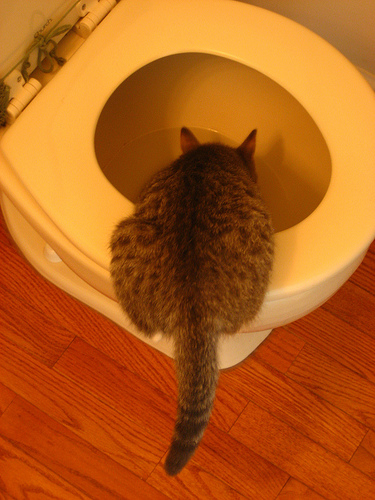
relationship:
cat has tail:
[108, 124, 264, 476] [162, 321, 215, 474]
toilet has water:
[3, 3, 374, 375] [124, 123, 247, 214]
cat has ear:
[108, 124, 264, 476] [180, 124, 198, 154]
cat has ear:
[108, 124, 264, 476] [241, 127, 261, 158]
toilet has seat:
[3, 3, 374, 375] [3, 4, 374, 312]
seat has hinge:
[3, 4, 374, 312] [8, 73, 44, 117]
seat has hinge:
[3, 4, 374, 312] [82, 4, 118, 32]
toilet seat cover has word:
[1, 1, 78, 80] [34, 17, 58, 43]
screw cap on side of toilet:
[6, 74, 25, 97] [3, 3, 374, 375]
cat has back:
[108, 124, 264, 476] [144, 161, 251, 277]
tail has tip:
[162, 321, 215, 474] [163, 443, 192, 476]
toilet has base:
[3, 3, 374, 375] [4, 195, 271, 378]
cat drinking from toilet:
[108, 124, 264, 476] [3, 3, 374, 375]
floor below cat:
[1, 204, 374, 499] [108, 124, 264, 476]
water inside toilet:
[124, 123, 247, 214] [3, 3, 374, 375]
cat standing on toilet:
[108, 124, 264, 476] [3, 3, 374, 375]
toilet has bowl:
[3, 3, 374, 375] [104, 56, 331, 231]